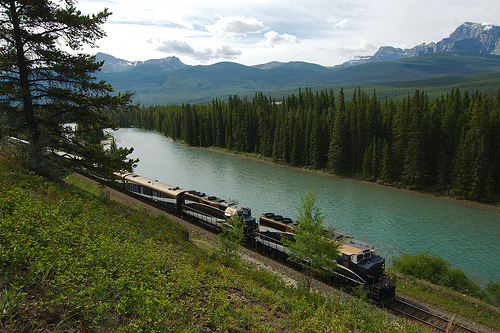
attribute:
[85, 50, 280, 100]
mountain — in distance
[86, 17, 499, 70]
mountains — tall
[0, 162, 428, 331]
grassy land — elevated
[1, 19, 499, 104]
mountains — tall 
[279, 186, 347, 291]
tree — small, green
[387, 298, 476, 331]
train tracks — brown 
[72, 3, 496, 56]
sky — cloudy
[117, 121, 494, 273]
river — green 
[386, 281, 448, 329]
tracks — train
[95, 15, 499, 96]
mountains — in distance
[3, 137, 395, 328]
hill — steep, grass, covered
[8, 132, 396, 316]
train — platform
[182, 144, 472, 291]
water — green , blue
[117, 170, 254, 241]
cars — train, being pulled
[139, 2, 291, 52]
clouds — white 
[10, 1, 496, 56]
sky — blue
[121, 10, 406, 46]
sky — blue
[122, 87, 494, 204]
trees — evergreen 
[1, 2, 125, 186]
tree — pine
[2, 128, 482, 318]
train — long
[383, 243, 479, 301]
brush — green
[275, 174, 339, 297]
tree — small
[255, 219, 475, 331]
tracks — railroad